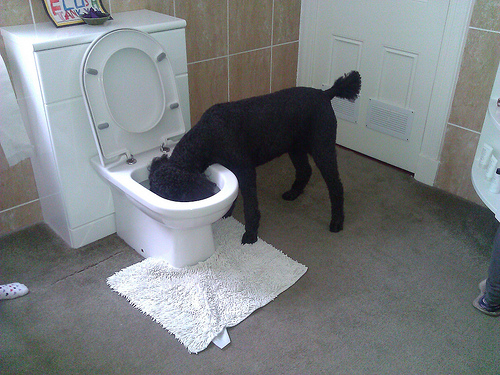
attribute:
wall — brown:
[0, 0, 307, 246]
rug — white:
[100, 206, 311, 356]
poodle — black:
[146, 65, 371, 247]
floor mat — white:
[103, 213, 310, 357]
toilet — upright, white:
[78, 29, 239, 266]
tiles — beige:
[187, 5, 294, 89]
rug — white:
[108, 213, 305, 348]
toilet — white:
[78, 25, 275, 300]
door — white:
[298, 1, 448, 174]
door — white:
[297, 2, 467, 187]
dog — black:
[158, 85, 363, 237]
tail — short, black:
[324, 63, 363, 104]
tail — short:
[328, 67, 361, 106]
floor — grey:
[372, 162, 494, 368]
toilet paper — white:
[0, 55, 37, 169]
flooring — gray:
[375, 185, 450, 240]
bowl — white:
[98, 147, 238, 261]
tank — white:
[3, 20, 195, 240]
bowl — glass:
[82, 11, 114, 27]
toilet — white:
[73, 19, 243, 272]